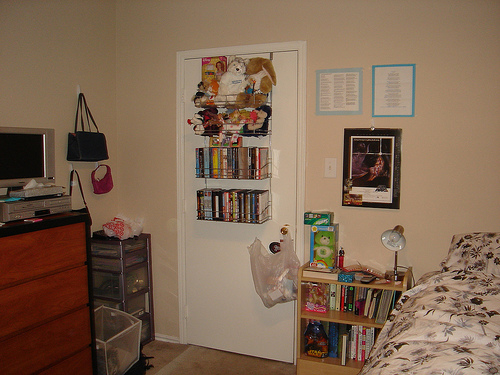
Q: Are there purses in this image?
A: Yes, there is a purse.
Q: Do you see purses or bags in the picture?
A: Yes, there is a purse.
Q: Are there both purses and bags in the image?
A: Yes, there are both a purse and a bag.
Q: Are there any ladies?
A: No, there are no ladies.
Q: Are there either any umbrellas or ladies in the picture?
A: No, there are no ladies or umbrellas.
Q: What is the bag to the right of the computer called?
A: The bag is a purse.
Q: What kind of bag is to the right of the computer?
A: The bag is a purse.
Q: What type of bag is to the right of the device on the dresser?
A: The bag is a purse.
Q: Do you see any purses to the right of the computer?
A: Yes, there is a purse to the right of the computer.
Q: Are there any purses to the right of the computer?
A: Yes, there is a purse to the right of the computer.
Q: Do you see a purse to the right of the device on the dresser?
A: Yes, there is a purse to the right of the computer.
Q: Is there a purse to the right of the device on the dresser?
A: Yes, there is a purse to the right of the computer.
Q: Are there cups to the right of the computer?
A: No, there is a purse to the right of the computer.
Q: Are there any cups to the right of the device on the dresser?
A: No, there is a purse to the right of the computer.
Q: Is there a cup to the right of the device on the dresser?
A: No, there is a purse to the right of the computer.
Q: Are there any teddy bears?
A: Yes, there is a teddy bear.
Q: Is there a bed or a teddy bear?
A: Yes, there is a teddy bear.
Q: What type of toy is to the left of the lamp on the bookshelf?
A: The toy is a teddy bear.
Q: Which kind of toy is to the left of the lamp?
A: The toy is a teddy bear.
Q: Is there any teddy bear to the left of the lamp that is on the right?
A: Yes, there is a teddy bear to the left of the lamp.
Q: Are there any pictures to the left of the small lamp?
A: No, there is a teddy bear to the left of the lamp.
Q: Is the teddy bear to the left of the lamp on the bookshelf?
A: Yes, the teddy bear is to the left of the lamp.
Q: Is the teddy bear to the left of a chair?
A: No, the teddy bear is to the left of the lamp.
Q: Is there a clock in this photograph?
A: No, there are no clocks.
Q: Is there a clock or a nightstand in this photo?
A: No, there are no clocks or nightstands.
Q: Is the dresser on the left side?
A: Yes, the dresser is on the left of the image.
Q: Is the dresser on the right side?
A: No, the dresser is on the left of the image.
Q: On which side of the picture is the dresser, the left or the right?
A: The dresser is on the left of the image.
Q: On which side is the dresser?
A: The dresser is on the left of the image.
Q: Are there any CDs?
A: No, there are no cds.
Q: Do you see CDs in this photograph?
A: No, there are no cds.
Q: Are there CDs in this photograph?
A: No, there are no cds.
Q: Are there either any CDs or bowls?
A: No, there are no CDs or bowls.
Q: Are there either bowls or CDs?
A: No, there are no CDs or bowls.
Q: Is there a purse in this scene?
A: Yes, there is a purse.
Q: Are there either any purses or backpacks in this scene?
A: Yes, there is a purse.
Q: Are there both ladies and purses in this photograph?
A: No, there is a purse but no ladies.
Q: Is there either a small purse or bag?
A: Yes, there is a small purse.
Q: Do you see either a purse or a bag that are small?
A: Yes, the purse is small.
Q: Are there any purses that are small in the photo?
A: Yes, there is a small purse.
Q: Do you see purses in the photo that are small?
A: Yes, there is a small purse.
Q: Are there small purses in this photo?
A: Yes, there is a small purse.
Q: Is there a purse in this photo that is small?
A: Yes, there is a purse that is small.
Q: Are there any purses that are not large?
A: Yes, there is a small purse.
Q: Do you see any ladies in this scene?
A: No, there are no ladies.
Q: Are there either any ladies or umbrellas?
A: No, there are no ladies or umbrellas.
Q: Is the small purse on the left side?
A: Yes, the purse is on the left of the image.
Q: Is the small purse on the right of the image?
A: No, the purse is on the left of the image.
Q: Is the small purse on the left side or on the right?
A: The purse is on the left of the image.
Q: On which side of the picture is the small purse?
A: The purse is on the left of the image.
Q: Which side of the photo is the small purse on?
A: The purse is on the left of the image.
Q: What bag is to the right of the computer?
A: The bag is a purse.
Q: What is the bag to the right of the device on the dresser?
A: The bag is a purse.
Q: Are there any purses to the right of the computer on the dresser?
A: Yes, there is a purse to the right of the computer.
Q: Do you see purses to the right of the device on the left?
A: Yes, there is a purse to the right of the computer.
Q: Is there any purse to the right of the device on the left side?
A: Yes, there is a purse to the right of the computer.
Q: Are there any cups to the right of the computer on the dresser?
A: No, there is a purse to the right of the computer.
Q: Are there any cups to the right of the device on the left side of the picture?
A: No, there is a purse to the right of the computer.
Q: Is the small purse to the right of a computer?
A: Yes, the purse is to the right of a computer.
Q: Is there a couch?
A: No, there are no couches.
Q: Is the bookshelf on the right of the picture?
A: Yes, the bookshelf is on the right of the image.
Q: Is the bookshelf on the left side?
A: No, the bookshelf is on the right of the image.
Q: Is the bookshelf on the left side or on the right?
A: The bookshelf is on the right of the image.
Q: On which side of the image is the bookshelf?
A: The bookshelf is on the right of the image.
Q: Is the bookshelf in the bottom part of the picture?
A: Yes, the bookshelf is in the bottom of the image.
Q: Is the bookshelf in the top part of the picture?
A: No, the bookshelf is in the bottom of the image.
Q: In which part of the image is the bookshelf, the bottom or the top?
A: The bookshelf is in the bottom of the image.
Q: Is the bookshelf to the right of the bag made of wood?
A: Yes, the bookshelf is made of wood.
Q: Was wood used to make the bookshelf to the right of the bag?
A: Yes, the bookshelf is made of wood.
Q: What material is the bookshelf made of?
A: The bookshelf is made of wood.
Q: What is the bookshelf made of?
A: The bookshelf is made of wood.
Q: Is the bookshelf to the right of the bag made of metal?
A: No, the bookshelf is made of wood.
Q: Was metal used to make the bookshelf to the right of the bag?
A: No, the bookshelf is made of wood.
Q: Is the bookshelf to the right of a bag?
A: Yes, the bookshelf is to the right of a bag.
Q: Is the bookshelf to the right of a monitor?
A: No, the bookshelf is to the right of a bag.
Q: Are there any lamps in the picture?
A: Yes, there is a lamp.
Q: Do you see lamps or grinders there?
A: Yes, there is a lamp.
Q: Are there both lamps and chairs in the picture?
A: No, there is a lamp but no chairs.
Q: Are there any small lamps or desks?
A: Yes, there is a small lamp.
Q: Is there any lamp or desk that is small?
A: Yes, the lamp is small.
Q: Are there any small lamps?
A: Yes, there is a small lamp.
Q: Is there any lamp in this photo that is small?
A: Yes, there is a lamp that is small.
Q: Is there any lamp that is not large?
A: Yes, there is a small lamp.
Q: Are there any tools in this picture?
A: No, there are no tools.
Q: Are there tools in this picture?
A: No, there are no tools.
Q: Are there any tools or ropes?
A: No, there are no tools or ropes.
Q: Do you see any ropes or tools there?
A: No, there are no tools or ropes.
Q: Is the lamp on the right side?
A: Yes, the lamp is on the right of the image.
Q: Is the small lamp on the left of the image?
A: No, the lamp is on the right of the image.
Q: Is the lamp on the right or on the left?
A: The lamp is on the right of the image.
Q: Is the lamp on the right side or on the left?
A: The lamp is on the right of the image.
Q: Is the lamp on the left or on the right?
A: The lamp is on the right of the image.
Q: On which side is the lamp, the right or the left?
A: The lamp is on the right of the image.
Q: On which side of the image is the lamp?
A: The lamp is on the right of the image.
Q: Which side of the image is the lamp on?
A: The lamp is on the right of the image.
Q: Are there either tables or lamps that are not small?
A: No, there is a lamp but it is small.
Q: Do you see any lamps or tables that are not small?
A: No, there is a lamp but it is small.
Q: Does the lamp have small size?
A: Yes, the lamp is small.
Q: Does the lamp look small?
A: Yes, the lamp is small.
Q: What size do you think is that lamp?
A: The lamp is small.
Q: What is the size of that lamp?
A: The lamp is small.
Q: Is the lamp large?
A: No, the lamp is small.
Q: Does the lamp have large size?
A: No, the lamp is small.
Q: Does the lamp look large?
A: No, the lamp is small.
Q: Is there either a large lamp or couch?
A: No, there is a lamp but it is small.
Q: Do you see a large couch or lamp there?
A: No, there is a lamp but it is small.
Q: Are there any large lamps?
A: No, there is a lamp but it is small.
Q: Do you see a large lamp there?
A: No, there is a lamp but it is small.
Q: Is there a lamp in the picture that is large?
A: No, there is a lamp but it is small.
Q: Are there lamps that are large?
A: No, there is a lamp but it is small.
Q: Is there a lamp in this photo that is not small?
A: No, there is a lamp but it is small.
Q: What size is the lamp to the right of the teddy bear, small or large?
A: The lamp is small.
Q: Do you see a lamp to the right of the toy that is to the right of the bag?
A: Yes, there is a lamp to the right of the teddy bear.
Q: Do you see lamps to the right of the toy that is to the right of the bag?
A: Yes, there is a lamp to the right of the teddy bear.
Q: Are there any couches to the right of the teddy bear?
A: No, there is a lamp to the right of the teddy bear.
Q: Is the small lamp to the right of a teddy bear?
A: Yes, the lamp is to the right of a teddy bear.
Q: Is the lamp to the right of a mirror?
A: No, the lamp is to the right of a teddy bear.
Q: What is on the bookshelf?
A: The lamp is on the bookshelf.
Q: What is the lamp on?
A: The lamp is on the bookshelf.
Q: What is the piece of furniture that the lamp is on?
A: The piece of furniture is a bookshelf.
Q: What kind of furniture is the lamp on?
A: The lamp is on the bookshelf.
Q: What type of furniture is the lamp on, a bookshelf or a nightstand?
A: The lamp is on a bookshelf.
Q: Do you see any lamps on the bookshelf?
A: Yes, there is a lamp on the bookshelf.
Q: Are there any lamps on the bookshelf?
A: Yes, there is a lamp on the bookshelf.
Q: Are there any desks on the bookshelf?
A: No, there is a lamp on the bookshelf.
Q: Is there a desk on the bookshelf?
A: No, there is a lamp on the bookshelf.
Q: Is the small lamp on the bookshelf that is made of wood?
A: Yes, the lamp is on the bookshelf.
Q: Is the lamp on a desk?
A: No, the lamp is on the bookshelf.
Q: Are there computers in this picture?
A: Yes, there is a computer.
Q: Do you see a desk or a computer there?
A: Yes, there is a computer.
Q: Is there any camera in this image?
A: No, there are no cameras.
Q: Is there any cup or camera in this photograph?
A: No, there are no cameras or cups.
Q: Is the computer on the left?
A: Yes, the computer is on the left of the image.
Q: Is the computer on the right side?
A: No, the computer is on the left of the image.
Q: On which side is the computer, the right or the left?
A: The computer is on the left of the image.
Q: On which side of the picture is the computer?
A: The computer is on the left of the image.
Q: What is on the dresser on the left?
A: The computer is on the dresser.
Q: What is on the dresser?
A: The computer is on the dresser.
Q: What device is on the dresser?
A: The device is a computer.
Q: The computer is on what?
A: The computer is on the dresser.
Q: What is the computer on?
A: The computer is on the dresser.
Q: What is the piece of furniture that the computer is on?
A: The piece of furniture is a dresser.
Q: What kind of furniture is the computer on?
A: The computer is on the dresser.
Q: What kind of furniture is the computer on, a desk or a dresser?
A: The computer is on a dresser.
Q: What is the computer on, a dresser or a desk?
A: The computer is on a dresser.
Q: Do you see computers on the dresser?
A: Yes, there is a computer on the dresser.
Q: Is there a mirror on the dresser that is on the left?
A: No, there is a computer on the dresser.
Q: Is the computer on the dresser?
A: Yes, the computer is on the dresser.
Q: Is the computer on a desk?
A: No, the computer is on the dresser.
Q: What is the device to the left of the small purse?
A: The device is a computer.